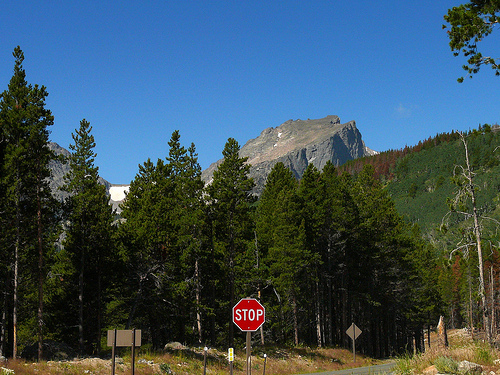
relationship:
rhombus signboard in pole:
[346, 320, 361, 338] [351, 337, 357, 362]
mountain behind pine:
[198, 114, 378, 194] [267, 186, 319, 345]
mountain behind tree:
[198, 114, 378, 194] [201, 135, 258, 352]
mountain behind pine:
[198, 114, 378, 194] [117, 159, 157, 268]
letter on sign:
[231, 307, 241, 322] [233, 297, 266, 331]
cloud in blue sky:
[390, 104, 412, 116] [19, 3, 496, 133]